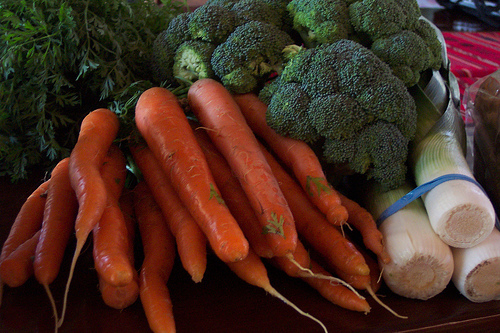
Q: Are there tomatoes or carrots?
A: Yes, there is a carrot.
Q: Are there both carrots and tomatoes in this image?
A: No, there is a carrot but no tomatoes.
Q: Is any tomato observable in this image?
A: No, there are no tomatoes.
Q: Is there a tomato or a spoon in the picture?
A: No, there are no tomatoes or spoons.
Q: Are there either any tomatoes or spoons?
A: No, there are no tomatoes or spoons.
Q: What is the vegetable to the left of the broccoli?
A: The vegetable is a carrot.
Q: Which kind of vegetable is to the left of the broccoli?
A: The vegetable is a carrot.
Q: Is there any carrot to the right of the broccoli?
A: No, the carrot is to the left of the broccoli.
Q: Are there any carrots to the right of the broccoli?
A: No, the carrot is to the left of the broccoli.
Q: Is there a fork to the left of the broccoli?
A: No, there is a carrot to the left of the broccoli.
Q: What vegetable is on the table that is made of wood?
A: The vegetable is a carrot.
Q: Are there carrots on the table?
A: Yes, there is a carrot on the table.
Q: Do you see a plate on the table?
A: No, there is a carrot on the table.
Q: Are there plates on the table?
A: No, there is a carrot on the table.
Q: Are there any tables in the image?
A: Yes, there is a table.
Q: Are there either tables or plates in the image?
A: Yes, there is a table.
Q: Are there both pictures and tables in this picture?
A: No, there is a table but no pictures.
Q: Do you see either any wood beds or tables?
A: Yes, there is a wood table.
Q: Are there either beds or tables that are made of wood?
A: Yes, the table is made of wood.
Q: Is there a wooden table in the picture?
A: Yes, there is a wood table.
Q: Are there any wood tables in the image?
A: Yes, there is a wood table.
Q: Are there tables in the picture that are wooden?
A: Yes, there is a table that is wooden.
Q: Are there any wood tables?
A: Yes, there is a table that is made of wood.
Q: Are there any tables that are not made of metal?
A: Yes, there is a table that is made of wood.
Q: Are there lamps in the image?
A: No, there are no lamps.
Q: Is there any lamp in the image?
A: No, there are no lamps.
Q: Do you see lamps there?
A: No, there are no lamps.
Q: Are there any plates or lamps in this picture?
A: No, there are no lamps or plates.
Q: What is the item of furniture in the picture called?
A: The piece of furniture is a table.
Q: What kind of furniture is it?
A: The piece of furniture is a table.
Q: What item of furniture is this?
A: This is a table.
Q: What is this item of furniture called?
A: This is a table.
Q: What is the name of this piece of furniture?
A: This is a table.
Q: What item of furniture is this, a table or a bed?
A: This is a table.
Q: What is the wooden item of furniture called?
A: The piece of furniture is a table.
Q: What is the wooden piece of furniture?
A: The piece of furniture is a table.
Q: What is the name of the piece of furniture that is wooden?
A: The piece of furniture is a table.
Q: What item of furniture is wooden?
A: The piece of furniture is a table.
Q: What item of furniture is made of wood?
A: The piece of furniture is a table.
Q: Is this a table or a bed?
A: This is a table.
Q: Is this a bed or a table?
A: This is a table.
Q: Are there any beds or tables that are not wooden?
A: No, there is a table but it is wooden.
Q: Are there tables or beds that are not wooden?
A: No, there is a table but it is wooden.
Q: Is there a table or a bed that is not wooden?
A: No, there is a table but it is wooden.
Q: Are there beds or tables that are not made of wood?
A: No, there is a table but it is made of wood.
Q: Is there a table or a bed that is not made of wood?
A: No, there is a table but it is made of wood.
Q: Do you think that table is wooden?
A: Yes, the table is wooden.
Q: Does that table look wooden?
A: Yes, the table is wooden.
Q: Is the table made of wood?
A: Yes, the table is made of wood.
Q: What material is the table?
A: The table is made of wood.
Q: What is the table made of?
A: The table is made of wood.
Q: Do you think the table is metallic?
A: No, the table is wooden.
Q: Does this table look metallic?
A: No, the table is wooden.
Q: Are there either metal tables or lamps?
A: No, there is a table but it is wooden.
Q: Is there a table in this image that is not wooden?
A: No, there is a table but it is wooden.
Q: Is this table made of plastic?
A: No, the table is made of wood.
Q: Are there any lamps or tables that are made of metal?
A: No, there is a table but it is made of wood.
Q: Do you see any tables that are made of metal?
A: No, there is a table but it is made of wood.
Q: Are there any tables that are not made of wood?
A: No, there is a table but it is made of wood.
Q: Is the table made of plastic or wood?
A: The table is made of wood.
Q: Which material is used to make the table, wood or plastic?
A: The table is made of wood.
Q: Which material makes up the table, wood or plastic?
A: The table is made of wood.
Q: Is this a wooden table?
A: Yes, this is a wooden table.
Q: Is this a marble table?
A: No, this is a wooden table.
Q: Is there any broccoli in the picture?
A: Yes, there is broccoli.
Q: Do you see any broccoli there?
A: Yes, there is broccoli.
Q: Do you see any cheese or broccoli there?
A: Yes, there is broccoli.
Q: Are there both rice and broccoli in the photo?
A: No, there is broccoli but no rice.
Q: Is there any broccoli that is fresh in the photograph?
A: Yes, there is fresh broccoli.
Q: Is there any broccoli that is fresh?
A: Yes, there is broccoli that is fresh.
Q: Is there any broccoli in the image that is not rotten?
A: Yes, there is fresh broccoli.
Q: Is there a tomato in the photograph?
A: No, there are no tomatoes.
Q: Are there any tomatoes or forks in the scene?
A: No, there are no tomatoes or forks.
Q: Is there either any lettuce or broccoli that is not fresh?
A: No, there is broccoli but it is fresh.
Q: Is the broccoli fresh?
A: Yes, the broccoli is fresh.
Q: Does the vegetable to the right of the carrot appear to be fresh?
A: Yes, the broccoli is fresh.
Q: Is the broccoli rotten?
A: No, the broccoli is fresh.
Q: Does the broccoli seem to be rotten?
A: No, the broccoli is fresh.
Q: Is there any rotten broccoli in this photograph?
A: No, there is broccoli but it is fresh.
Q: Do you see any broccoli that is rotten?
A: No, there is broccoli but it is fresh.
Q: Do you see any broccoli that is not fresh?
A: No, there is broccoli but it is fresh.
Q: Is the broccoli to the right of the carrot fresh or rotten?
A: The broccoli is fresh.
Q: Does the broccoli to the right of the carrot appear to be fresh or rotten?
A: The broccoli is fresh.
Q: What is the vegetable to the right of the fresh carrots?
A: The vegetable is broccoli.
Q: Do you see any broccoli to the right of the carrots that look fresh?
A: Yes, there is broccoli to the right of the carrots.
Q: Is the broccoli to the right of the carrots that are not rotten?
A: Yes, the broccoli is to the right of the carrots.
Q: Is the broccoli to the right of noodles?
A: No, the broccoli is to the right of the carrots.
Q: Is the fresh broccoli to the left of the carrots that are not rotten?
A: No, the broccoli is to the right of the carrots.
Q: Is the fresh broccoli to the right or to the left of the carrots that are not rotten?
A: The broccoli is to the right of the carrots.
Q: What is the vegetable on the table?
A: The vegetable is broccoli.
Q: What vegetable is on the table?
A: The vegetable is broccoli.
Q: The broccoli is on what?
A: The broccoli is on the table.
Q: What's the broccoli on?
A: The broccoli is on the table.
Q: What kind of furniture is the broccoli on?
A: The broccoli is on the table.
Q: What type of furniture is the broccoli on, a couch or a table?
A: The broccoli is on a table.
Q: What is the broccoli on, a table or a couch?
A: The broccoli is on a table.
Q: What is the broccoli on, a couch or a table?
A: The broccoli is on a table.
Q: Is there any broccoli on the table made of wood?
A: Yes, there is broccoli on the table.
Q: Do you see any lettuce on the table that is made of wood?
A: No, there is broccoli on the table.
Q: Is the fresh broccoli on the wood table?
A: Yes, the broccoli is on the table.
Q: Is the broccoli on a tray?
A: No, the broccoli is on the table.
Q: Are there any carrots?
A: Yes, there are carrots.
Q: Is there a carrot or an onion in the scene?
A: Yes, there are carrots.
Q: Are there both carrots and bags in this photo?
A: No, there are carrots but no bags.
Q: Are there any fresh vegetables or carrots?
A: Yes, there are fresh carrots.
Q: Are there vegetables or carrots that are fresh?
A: Yes, the carrots are fresh.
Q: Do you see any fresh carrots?
A: Yes, there are fresh carrots.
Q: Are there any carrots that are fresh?
A: Yes, there are carrots that are fresh.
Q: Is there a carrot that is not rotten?
A: Yes, there are fresh carrots.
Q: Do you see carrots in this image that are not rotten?
A: Yes, there are fresh carrots.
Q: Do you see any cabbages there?
A: No, there are no cabbages.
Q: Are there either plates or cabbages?
A: No, there are no cabbages or plates.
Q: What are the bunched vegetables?
A: The vegetables are carrots.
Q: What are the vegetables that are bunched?
A: The vegetables are carrots.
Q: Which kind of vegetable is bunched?
A: The vegetable is carrots.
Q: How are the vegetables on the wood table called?
A: The vegetables are carrots.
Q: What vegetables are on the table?
A: The vegetables are carrots.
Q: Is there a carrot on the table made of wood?
A: Yes, there are carrots on the table.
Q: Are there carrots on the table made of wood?
A: Yes, there are carrots on the table.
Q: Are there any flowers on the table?
A: No, there are carrots on the table.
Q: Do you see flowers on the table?
A: No, there are carrots on the table.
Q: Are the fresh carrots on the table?
A: Yes, the carrots are on the table.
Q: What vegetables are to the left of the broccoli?
A: The vegetables are carrots.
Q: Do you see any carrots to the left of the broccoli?
A: Yes, there are carrots to the left of the broccoli.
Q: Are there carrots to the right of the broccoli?
A: No, the carrots are to the left of the broccoli.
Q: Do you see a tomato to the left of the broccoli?
A: No, there are carrots to the left of the broccoli.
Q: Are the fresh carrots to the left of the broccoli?
A: Yes, the carrots are to the left of the broccoli.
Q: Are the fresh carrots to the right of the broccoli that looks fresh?
A: No, the carrots are to the left of the broccoli.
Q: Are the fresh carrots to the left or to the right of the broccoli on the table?
A: The carrots are to the left of the broccoli.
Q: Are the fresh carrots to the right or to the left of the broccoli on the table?
A: The carrots are to the left of the broccoli.